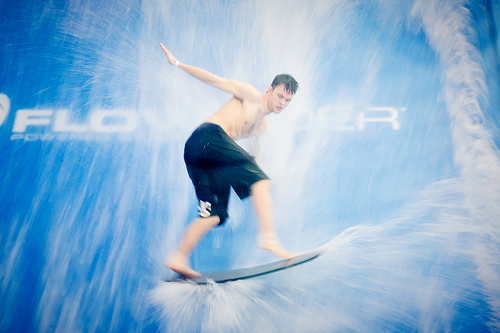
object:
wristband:
[174, 60, 180, 67]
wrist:
[173, 60, 184, 68]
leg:
[225, 157, 277, 239]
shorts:
[180, 121, 267, 229]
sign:
[8, 107, 405, 141]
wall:
[0, 0, 500, 333]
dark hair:
[266, 74, 299, 94]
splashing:
[0, 0, 499, 333]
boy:
[159, 42, 301, 277]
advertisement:
[0, 93, 401, 142]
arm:
[179, 62, 251, 100]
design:
[198, 200, 211, 218]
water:
[0, 0, 500, 333]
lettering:
[9, 107, 400, 134]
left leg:
[174, 164, 230, 258]